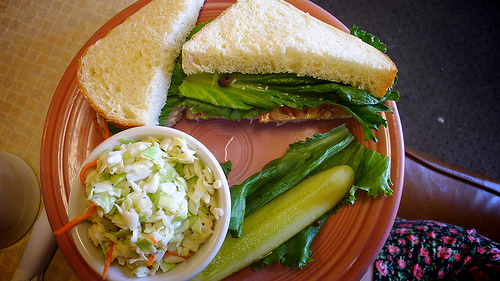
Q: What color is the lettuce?
A: Green.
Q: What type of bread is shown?
A: White.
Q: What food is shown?
A: A sandwich.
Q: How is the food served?
A: On a plate.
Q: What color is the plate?
A: Orange.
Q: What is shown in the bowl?
A: Slaw.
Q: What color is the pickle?
A: Green.